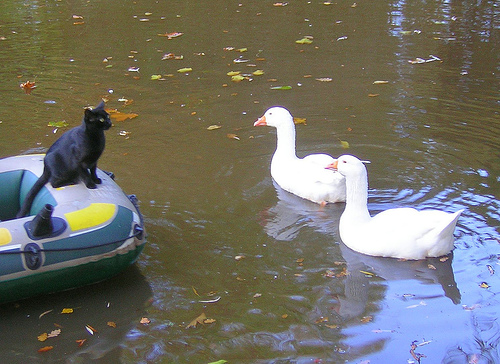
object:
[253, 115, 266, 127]
beak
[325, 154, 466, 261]
ducks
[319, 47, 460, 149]
pond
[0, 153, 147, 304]
boat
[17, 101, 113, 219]
cat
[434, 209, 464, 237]
tail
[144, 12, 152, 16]
leaves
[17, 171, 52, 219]
tail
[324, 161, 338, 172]
beaks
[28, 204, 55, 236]
tube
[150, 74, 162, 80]
leaves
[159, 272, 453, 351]
water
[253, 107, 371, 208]
duck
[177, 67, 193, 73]
leaves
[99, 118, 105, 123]
eyes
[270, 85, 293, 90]
leaf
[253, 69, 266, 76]
leaf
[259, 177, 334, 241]
goose reflection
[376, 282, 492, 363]
sky reflection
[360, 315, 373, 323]
leaf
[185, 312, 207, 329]
leaf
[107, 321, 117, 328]
leaf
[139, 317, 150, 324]
leaf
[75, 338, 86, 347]
leaf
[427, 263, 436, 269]
leaf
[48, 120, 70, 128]
leaf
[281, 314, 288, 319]
leaf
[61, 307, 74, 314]
leaf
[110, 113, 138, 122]
leaf